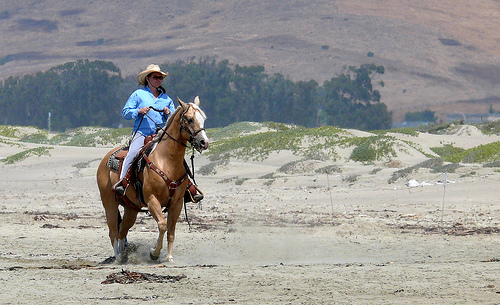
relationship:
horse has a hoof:
[97, 96, 209, 263] [151, 248, 162, 260]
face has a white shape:
[187, 111, 208, 142] [195, 111, 207, 139]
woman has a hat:
[115, 63, 204, 201] [139, 64, 169, 85]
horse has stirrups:
[97, 96, 209, 263] [113, 165, 204, 203]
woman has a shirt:
[115, 63, 204, 201] [122, 85, 176, 136]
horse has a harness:
[97, 96, 209, 263] [117, 147, 188, 212]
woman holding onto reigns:
[115, 63, 204, 201] [130, 106, 196, 147]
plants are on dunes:
[1, 121, 499, 168] [0, 121, 499, 194]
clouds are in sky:
[2, 1, 499, 131] [2, 1, 500, 130]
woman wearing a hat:
[115, 63, 204, 201] [139, 64, 169, 85]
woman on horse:
[115, 63, 204, 201] [97, 96, 209, 263]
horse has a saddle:
[97, 96, 209, 263] [144, 135, 159, 145]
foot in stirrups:
[116, 182, 127, 194] [113, 165, 204, 203]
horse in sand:
[97, 96, 209, 263] [1, 120, 500, 305]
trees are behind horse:
[0, 7, 500, 131] [97, 96, 209, 263]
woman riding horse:
[115, 63, 204, 201] [97, 96, 209, 263]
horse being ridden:
[97, 96, 209, 263] [97, 63, 209, 263]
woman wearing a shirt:
[115, 63, 204, 201] [122, 85, 176, 136]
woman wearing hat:
[115, 63, 204, 201] [139, 64, 169, 85]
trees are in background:
[0, 7, 500, 131] [1, 0, 499, 129]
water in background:
[390, 121, 430, 128] [1, 0, 499, 129]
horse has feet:
[97, 96, 209, 263] [113, 238, 175, 265]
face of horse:
[187, 111, 208, 142] [68, 91, 217, 288]